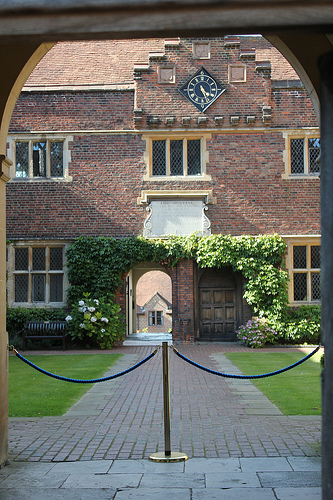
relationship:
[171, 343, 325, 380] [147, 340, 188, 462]
rope connected to post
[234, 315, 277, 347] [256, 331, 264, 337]
bush with flower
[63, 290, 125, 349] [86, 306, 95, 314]
bush with flower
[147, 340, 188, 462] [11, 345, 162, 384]
post holding rope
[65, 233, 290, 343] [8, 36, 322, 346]
foliage growing up wall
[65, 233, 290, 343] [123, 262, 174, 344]
foliage growing over walkway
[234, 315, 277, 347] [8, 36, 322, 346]
bush in front of wall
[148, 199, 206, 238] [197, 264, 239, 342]
plaque over door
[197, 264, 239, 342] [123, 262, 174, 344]
door near walkway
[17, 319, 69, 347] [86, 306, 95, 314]
bench next to flower